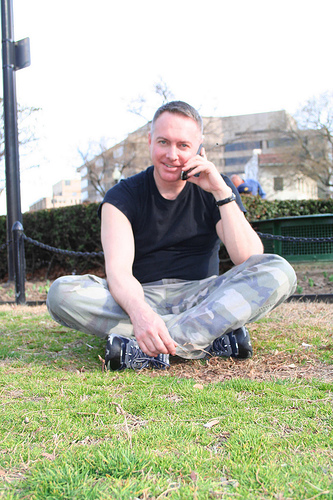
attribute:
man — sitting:
[42, 100, 298, 370]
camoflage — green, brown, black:
[170, 284, 232, 330]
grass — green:
[0, 301, 333, 498]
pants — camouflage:
[44, 252, 297, 358]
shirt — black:
[109, 168, 257, 293]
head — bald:
[230, 170, 243, 182]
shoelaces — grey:
[123, 344, 166, 369]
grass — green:
[13, 369, 332, 498]